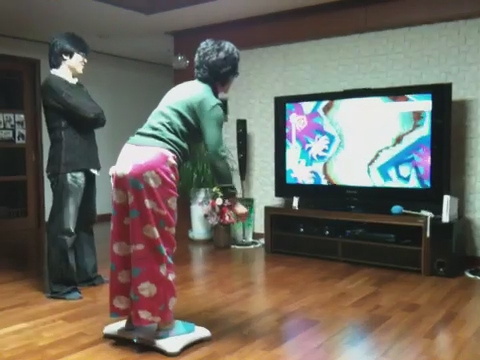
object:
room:
[0, 0, 479, 360]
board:
[102, 318, 212, 357]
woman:
[107, 38, 248, 339]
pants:
[108, 143, 179, 326]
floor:
[0, 220, 480, 360]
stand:
[264, 203, 453, 277]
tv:
[274, 82, 452, 211]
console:
[441, 194, 458, 223]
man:
[40, 31, 110, 300]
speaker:
[236, 119, 247, 181]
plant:
[181, 142, 237, 200]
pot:
[187, 187, 215, 241]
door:
[0, 53, 48, 277]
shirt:
[127, 79, 238, 199]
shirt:
[40, 68, 107, 174]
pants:
[47, 170, 105, 299]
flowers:
[202, 198, 236, 226]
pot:
[213, 222, 231, 249]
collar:
[50, 69, 79, 85]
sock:
[155, 320, 195, 339]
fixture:
[170, 53, 189, 70]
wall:
[236, 4, 479, 95]